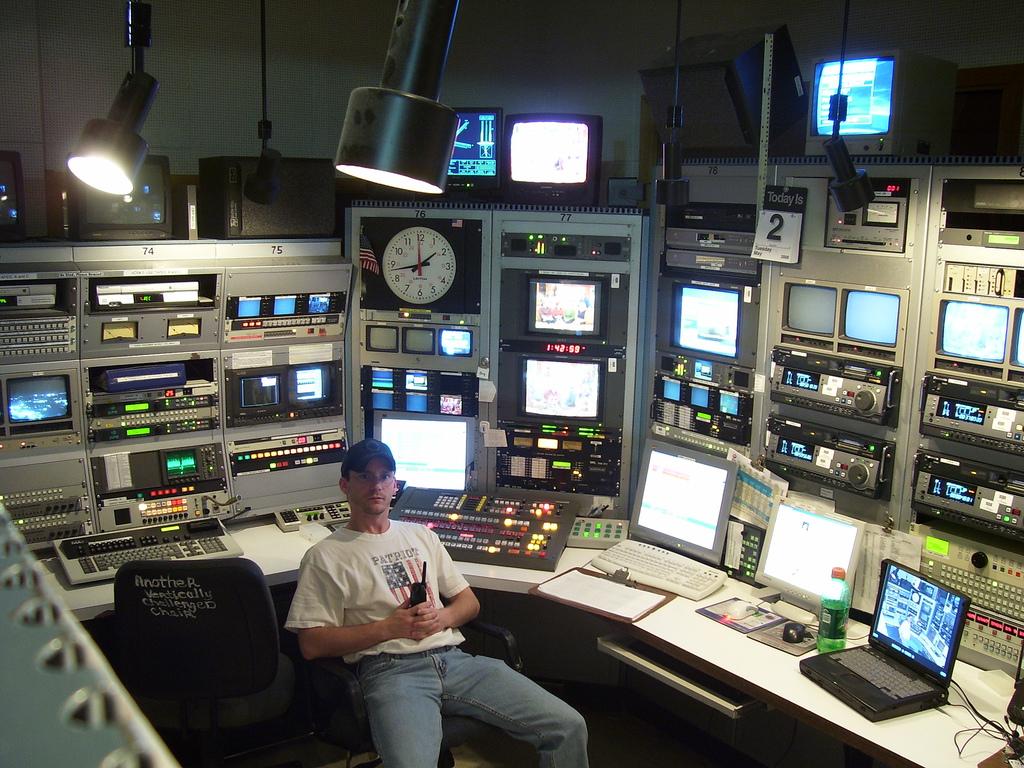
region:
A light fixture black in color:
[56, 24, 170, 217]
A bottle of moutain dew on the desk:
[805, 557, 863, 658]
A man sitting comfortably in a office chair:
[298, 418, 601, 766]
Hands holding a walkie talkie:
[391, 552, 462, 643]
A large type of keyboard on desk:
[36, 508, 246, 590]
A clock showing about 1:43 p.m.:
[329, 202, 490, 316]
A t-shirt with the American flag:
[341, 537, 466, 644]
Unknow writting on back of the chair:
[103, 545, 292, 712]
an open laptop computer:
[797, 557, 971, 722]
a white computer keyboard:
[590, 535, 724, 602]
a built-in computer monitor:
[627, 440, 745, 564]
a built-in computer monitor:
[841, 288, 899, 349]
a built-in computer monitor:
[940, 301, 1005, 363]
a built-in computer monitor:
[373, 415, 475, 499]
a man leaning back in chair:
[283, 441, 590, 762]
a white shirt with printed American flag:
[276, 525, 472, 666]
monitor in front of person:
[239, 296, 263, 320]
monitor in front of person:
[273, 296, 297, 313]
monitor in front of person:
[511, 120, 592, 185]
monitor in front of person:
[871, 559, 965, 676]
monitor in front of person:
[761, 503, 857, 611]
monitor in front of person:
[639, 449, 729, 552]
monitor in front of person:
[671, 282, 743, 360]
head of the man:
[310, 395, 462, 558]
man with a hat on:
[249, 342, 509, 665]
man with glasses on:
[269, 382, 520, 576]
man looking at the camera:
[186, 338, 598, 700]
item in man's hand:
[334, 543, 470, 670]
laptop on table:
[758, 530, 999, 753]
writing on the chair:
[88, 500, 295, 700]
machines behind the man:
[72, 246, 415, 535]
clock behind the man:
[326, 192, 508, 341]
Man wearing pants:
[337, 639, 606, 766]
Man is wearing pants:
[339, 637, 600, 765]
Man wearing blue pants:
[336, 627, 613, 765]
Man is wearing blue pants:
[337, 639, 606, 766]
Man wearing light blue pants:
[332, 637, 601, 765]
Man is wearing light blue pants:
[348, 636, 605, 764]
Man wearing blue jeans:
[351, 640, 598, 765]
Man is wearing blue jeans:
[343, 640, 600, 765]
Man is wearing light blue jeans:
[329, 634, 608, 765]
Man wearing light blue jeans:
[345, 631, 599, 765]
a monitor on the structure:
[856, 277, 895, 344]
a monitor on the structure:
[770, 304, 825, 378]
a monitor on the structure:
[875, 563, 943, 628]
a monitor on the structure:
[702, 255, 741, 326]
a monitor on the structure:
[531, 256, 589, 307]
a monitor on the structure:
[362, 401, 467, 500]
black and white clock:
[371, 221, 476, 314]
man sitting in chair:
[277, 435, 575, 762]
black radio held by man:
[403, 549, 452, 619]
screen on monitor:
[11, 358, 81, 416]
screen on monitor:
[807, 560, 979, 732]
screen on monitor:
[611, 443, 739, 568]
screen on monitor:
[512, 101, 602, 182]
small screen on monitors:
[231, 294, 336, 323]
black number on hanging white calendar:
[753, 204, 798, 255]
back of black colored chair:
[111, 546, 289, 724]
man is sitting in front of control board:
[283, 435, 597, 767]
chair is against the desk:
[103, 560, 312, 763]